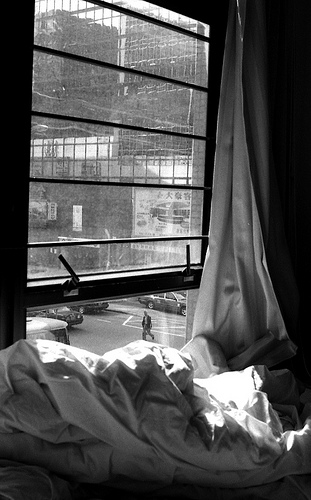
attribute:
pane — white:
[92, 165, 184, 247]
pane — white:
[29, 179, 205, 238]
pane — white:
[30, 112, 212, 188]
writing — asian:
[155, 192, 164, 199]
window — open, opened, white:
[19, 0, 222, 382]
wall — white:
[34, 0, 211, 267]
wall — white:
[126, 164, 193, 257]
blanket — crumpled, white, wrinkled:
[1, 335, 310, 483]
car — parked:
[89, 257, 204, 317]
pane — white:
[174, 153, 188, 179]